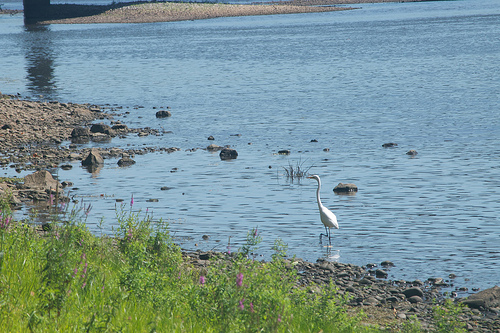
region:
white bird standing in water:
[301, 178, 347, 254]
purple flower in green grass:
[228, 268, 248, 287]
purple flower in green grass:
[191, 268, 217, 290]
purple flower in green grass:
[239, 303, 249, 314]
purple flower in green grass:
[267, 310, 283, 327]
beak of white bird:
[301, 170, 315, 181]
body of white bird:
[317, 207, 342, 227]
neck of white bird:
[306, 182, 323, 202]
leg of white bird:
[318, 231, 325, 242]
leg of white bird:
[323, 235, 333, 244]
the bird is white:
[305, 170, 347, 237]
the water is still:
[356, 50, 454, 102]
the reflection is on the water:
[20, 38, 68, 85]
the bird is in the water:
[304, 172, 350, 245]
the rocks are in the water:
[72, 91, 267, 188]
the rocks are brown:
[48, 109, 265, 199]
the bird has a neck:
[307, 184, 327, 207]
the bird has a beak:
[302, 171, 315, 186]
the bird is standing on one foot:
[296, 161, 346, 245]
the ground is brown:
[100, 0, 274, 25]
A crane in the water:
[305, 166, 347, 251]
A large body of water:
[11, 17, 499, 268]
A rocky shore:
[40, 0, 340, 29]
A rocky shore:
[4, 85, 479, 322]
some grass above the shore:
[1, 237, 395, 332]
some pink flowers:
[197, 270, 267, 312]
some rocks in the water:
[328, 138, 433, 204]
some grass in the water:
[274, 162, 322, 181]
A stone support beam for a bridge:
[18, 0, 63, 23]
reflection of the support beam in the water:
[10, 23, 74, 91]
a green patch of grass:
[7, 218, 311, 331]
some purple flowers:
[59, 225, 279, 309]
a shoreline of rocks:
[12, 189, 495, 331]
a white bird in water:
[289, 164, 347, 249]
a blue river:
[12, 17, 496, 242]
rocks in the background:
[34, 0, 355, 36]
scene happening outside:
[17, 12, 497, 288]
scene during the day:
[15, 20, 473, 331]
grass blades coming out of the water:
[271, 152, 319, 189]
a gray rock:
[329, 176, 368, 199]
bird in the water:
[302, 172, 342, 249]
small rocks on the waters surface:
[146, 105, 419, 193]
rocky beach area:
[2, 86, 159, 211]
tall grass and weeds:
[20, 233, 251, 330]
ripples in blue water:
[100, 33, 438, 110]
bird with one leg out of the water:
[307, 176, 345, 258]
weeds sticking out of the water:
[279, 156, 317, 181]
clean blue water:
[168, 34, 494, 249]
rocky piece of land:
[37, 0, 349, 26]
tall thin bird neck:
[306, 169, 323, 201]